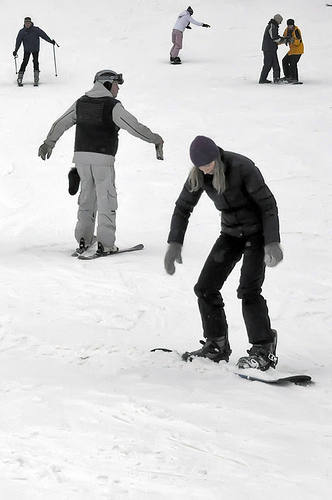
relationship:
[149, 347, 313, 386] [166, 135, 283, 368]
snowboard under person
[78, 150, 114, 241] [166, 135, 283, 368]
gray pants on person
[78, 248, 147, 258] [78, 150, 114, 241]
skis under person in gray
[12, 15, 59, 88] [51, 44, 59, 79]
two ski poles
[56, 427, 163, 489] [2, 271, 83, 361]
white snow on ground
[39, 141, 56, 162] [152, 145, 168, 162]
gloves on hand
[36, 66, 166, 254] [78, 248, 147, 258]
people walking on skis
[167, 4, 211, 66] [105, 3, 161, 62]
snowboarder snowboarding down slopes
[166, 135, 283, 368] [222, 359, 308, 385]
person on snowboard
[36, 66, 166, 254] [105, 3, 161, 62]
people skiing down slopes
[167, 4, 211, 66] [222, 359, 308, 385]
snowboarder standing on snowboard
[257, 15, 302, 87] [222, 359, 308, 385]
two people trying to snowboard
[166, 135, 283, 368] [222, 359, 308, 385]
person leaning to snowboard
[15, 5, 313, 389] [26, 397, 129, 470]
people on snow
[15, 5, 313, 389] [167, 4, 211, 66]
people skiing and snowboarder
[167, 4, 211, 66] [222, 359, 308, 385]
snowboarder on snowboard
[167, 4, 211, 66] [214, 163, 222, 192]
snowboarder with long hair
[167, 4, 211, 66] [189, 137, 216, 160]
snowboarder wearing a beanie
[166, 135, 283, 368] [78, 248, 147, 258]
person on skis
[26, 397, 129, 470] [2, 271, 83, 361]
snow covering ground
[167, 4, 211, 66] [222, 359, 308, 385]
snowboarder balancing on snowboard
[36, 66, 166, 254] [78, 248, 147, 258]
people walking with skis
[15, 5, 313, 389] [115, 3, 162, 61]
people enjoying slopes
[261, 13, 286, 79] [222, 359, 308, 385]
man teaching how to snowboard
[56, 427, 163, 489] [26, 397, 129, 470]
white fresh snow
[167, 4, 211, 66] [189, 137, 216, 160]
snowboarder wearing beanie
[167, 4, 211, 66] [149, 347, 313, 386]
snowboarder with black snowboard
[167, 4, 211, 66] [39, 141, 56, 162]
snowboarder wearing gray gloves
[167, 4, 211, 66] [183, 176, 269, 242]
snowboarder wearing black jacket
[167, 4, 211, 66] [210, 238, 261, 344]
snowboarder wearing black pants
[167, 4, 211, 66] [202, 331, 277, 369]
snowboarder wearing black boots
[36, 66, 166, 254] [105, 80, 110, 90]
people wearing black ear muffs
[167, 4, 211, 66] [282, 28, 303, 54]
snowboarder wearing yellow jacket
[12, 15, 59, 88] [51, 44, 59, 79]
person holding poles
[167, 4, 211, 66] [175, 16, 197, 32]
snowboarder wearing white hoodie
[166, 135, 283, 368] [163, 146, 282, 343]
person dressed in clothing